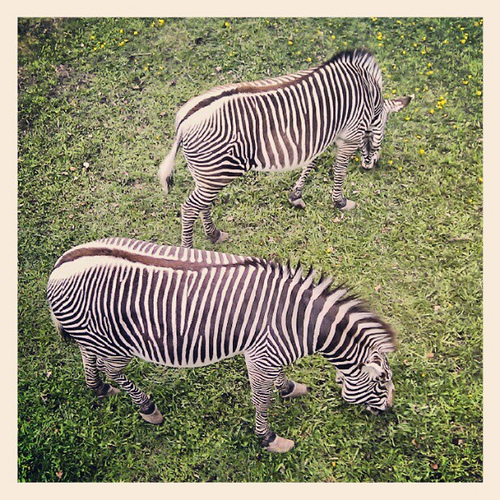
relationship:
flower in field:
[17, 18, 481, 164] [16, 17, 480, 481]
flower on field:
[17, 18, 481, 164] [16, 17, 480, 481]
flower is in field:
[17, 18, 481, 164] [16, 17, 480, 481]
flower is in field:
[372, 30, 383, 42] [16, 17, 480, 481]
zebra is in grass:
[47, 232, 396, 457] [18, 16, 483, 483]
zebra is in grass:
[157, 49, 415, 251] [18, 16, 483, 483]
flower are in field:
[17, 18, 481, 164] [16, 17, 480, 481]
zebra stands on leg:
[47, 232, 396, 457] [243, 352, 294, 454]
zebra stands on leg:
[47, 232, 396, 457] [272, 366, 309, 399]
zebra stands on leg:
[47, 232, 396, 457] [102, 353, 159, 428]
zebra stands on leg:
[47, 232, 396, 457] [74, 337, 106, 397]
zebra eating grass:
[157, 49, 415, 251] [18, 16, 483, 483]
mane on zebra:
[246, 247, 400, 362] [30, 237, 408, 462]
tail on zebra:
[48, 301, 78, 349] [47, 232, 396, 457]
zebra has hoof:
[47, 232, 396, 457] [139, 403, 167, 429]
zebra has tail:
[157, 49, 415, 251] [136, 122, 198, 226]